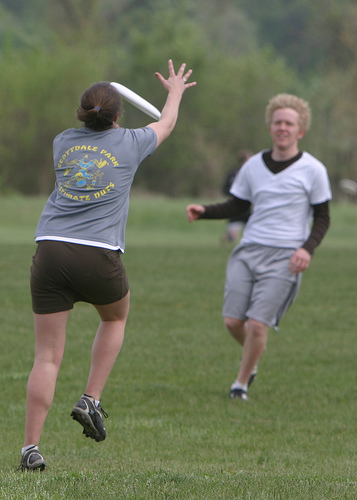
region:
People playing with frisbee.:
[111, 62, 180, 148]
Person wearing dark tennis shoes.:
[22, 405, 129, 482]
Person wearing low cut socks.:
[8, 437, 70, 466]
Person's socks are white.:
[23, 408, 59, 468]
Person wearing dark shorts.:
[25, 247, 119, 307]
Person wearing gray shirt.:
[47, 164, 138, 239]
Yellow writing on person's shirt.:
[59, 145, 125, 205]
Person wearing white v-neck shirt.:
[247, 164, 304, 224]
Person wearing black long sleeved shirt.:
[216, 166, 343, 260]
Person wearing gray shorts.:
[236, 246, 291, 318]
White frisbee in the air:
[89, 57, 164, 129]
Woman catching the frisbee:
[25, 47, 198, 472]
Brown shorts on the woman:
[12, 228, 133, 341]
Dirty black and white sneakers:
[17, 396, 120, 489]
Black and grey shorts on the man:
[196, 217, 322, 351]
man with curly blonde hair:
[223, 73, 335, 180]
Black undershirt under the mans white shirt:
[196, 139, 336, 281]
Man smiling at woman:
[189, 71, 352, 412]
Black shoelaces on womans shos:
[93, 403, 110, 429]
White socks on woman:
[82, 396, 104, 407]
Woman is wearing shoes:
[14, 391, 114, 475]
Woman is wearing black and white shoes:
[20, 393, 106, 479]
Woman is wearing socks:
[16, 390, 102, 455]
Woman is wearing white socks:
[19, 390, 101, 455]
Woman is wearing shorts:
[29, 233, 134, 316]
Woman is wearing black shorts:
[29, 234, 133, 315]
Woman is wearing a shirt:
[35, 120, 158, 248]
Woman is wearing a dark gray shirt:
[35, 124, 157, 247]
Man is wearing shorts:
[217, 237, 306, 337]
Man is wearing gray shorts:
[219, 238, 306, 336]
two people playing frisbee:
[18, 55, 339, 476]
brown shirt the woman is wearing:
[25, 235, 131, 316]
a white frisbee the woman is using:
[108, 77, 163, 122]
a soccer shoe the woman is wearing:
[67, 390, 110, 444]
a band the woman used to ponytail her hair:
[92, 104, 102, 113]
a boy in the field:
[184, 93, 334, 412]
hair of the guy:
[260, 91, 313, 108]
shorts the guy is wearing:
[218, 236, 308, 330]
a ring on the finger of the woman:
[180, 76, 187, 82]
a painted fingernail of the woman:
[153, 71, 158, 77]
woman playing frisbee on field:
[50, 92, 179, 396]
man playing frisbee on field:
[230, 100, 347, 343]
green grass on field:
[150, 412, 260, 465]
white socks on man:
[231, 370, 248, 390]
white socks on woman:
[27, 448, 52, 460]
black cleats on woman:
[52, 401, 123, 455]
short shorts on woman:
[34, 249, 103, 308]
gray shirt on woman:
[52, 128, 151, 250]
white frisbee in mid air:
[112, 73, 164, 127]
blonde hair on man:
[255, 91, 312, 128]